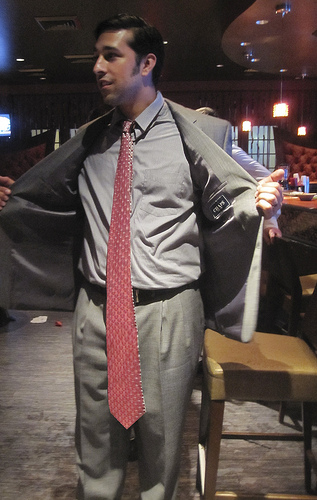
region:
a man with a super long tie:
[14, 23, 287, 459]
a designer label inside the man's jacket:
[205, 199, 237, 224]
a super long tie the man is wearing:
[94, 116, 156, 430]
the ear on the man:
[136, 51, 164, 79]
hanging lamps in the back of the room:
[223, 69, 313, 151]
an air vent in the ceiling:
[28, 12, 85, 35]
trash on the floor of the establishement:
[16, 305, 77, 336]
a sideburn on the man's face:
[123, 49, 151, 80]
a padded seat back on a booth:
[259, 125, 314, 192]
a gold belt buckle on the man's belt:
[130, 285, 141, 307]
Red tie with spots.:
[102, 116, 146, 437]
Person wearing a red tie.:
[0, 12, 287, 496]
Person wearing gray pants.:
[0, 9, 289, 498]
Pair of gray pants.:
[64, 266, 216, 489]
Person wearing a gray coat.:
[1, 10, 291, 499]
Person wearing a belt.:
[2, 11, 294, 496]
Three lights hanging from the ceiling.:
[234, 48, 311, 147]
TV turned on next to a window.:
[0, 90, 53, 145]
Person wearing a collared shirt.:
[5, 11, 289, 495]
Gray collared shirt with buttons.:
[70, 93, 200, 295]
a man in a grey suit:
[4, 11, 283, 492]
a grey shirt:
[75, 98, 198, 282]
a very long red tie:
[105, 117, 143, 430]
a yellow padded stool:
[189, 317, 308, 493]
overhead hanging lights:
[260, 74, 290, 122]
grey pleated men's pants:
[65, 291, 204, 497]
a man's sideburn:
[125, 54, 141, 78]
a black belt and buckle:
[80, 285, 189, 302]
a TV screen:
[0, 108, 13, 135]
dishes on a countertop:
[278, 184, 316, 208]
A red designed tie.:
[105, 115, 146, 430]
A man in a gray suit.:
[5, 12, 274, 498]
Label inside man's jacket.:
[208, 195, 236, 225]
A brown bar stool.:
[196, 327, 314, 498]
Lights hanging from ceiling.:
[271, 65, 315, 139]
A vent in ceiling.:
[28, 10, 84, 42]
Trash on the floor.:
[28, 313, 63, 336]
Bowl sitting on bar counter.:
[293, 190, 315, 205]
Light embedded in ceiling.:
[248, 15, 270, 34]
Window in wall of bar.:
[247, 121, 283, 173]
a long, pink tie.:
[98, 114, 162, 432]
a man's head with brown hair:
[80, 8, 169, 112]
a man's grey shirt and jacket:
[3, 99, 294, 343]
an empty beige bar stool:
[183, 238, 311, 481]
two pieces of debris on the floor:
[18, 304, 68, 339]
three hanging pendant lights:
[213, 40, 308, 138]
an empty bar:
[198, 7, 313, 401]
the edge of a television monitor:
[2, 103, 15, 140]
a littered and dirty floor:
[1, 308, 77, 492]